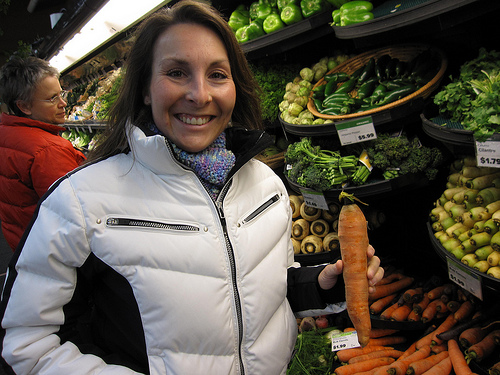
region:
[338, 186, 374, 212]
the top of carrot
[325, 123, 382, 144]
green and white sign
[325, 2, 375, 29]
a large green pepper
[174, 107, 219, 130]
the teeth on the woman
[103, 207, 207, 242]
a zipper on jacket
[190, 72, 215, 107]
nose on the lady in white jacket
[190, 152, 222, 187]
neck scarf on woman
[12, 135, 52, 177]
portion of orange jacket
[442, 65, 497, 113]
a leafy green vegetable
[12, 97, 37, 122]
an ear on woman in orange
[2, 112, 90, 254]
red puffy coat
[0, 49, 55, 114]
woman with short gray hair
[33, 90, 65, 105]
woman wearing glasses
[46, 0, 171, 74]
light above produce display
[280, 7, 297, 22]
green pepper next to green pepper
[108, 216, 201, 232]
zipper on white jacket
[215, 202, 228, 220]
silver metal zipper pull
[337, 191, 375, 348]
large orange carrot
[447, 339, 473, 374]
carrot next to carrot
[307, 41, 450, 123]
basket of peppers in display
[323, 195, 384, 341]
long carrot in woman's hand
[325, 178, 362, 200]
small top of carrot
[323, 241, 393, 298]
woman's fingers around the orange carrot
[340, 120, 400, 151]
white sign on basket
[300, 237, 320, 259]
black top of turnip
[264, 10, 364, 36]
green peppers on shelf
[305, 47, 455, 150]
basket filled with green chili peppers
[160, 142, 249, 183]
blue and red scarf around woman's neck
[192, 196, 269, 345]
long black zipper on jacket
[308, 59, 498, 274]
stand filled with vegetables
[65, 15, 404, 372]
a women wearing a white and black jacket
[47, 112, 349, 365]
a white and black jacket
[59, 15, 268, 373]
a women wearing a thick jacket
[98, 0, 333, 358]
a wome that is smiling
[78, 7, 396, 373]
a women holding a carrot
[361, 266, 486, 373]
a pile of carrots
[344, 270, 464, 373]
carrots that are for sale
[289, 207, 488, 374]
carrots for sale inside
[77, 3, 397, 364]
women in a grocery store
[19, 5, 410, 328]
women at a market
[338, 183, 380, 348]
an orange carrot at the supermarket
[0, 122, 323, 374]
a lady wearing a black and white ski jacket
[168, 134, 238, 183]
the lady is wearing a multi colored scarf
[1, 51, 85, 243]
a lady wearing a red ski jacket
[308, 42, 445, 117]
a basket of green jalapenos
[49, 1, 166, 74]
fluorescent lighting over the vegetables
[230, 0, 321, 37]
a rack of green peppers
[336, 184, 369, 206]
the carrots stem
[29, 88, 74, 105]
the lady has wire framed glasses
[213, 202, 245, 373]
the zipper of the ski jacket